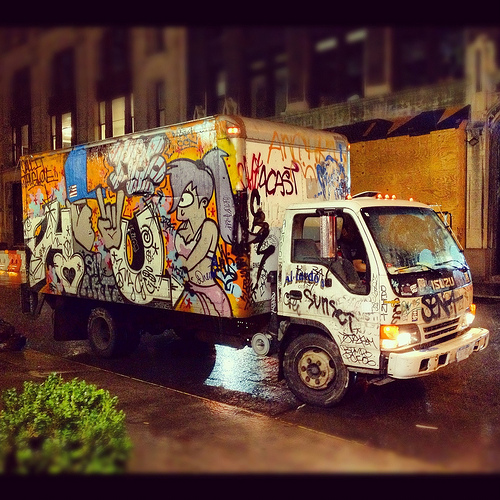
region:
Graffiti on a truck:
[191, 277, 256, 335]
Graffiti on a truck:
[298, 276, 338, 321]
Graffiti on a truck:
[332, 326, 382, 397]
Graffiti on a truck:
[394, 291, 493, 317]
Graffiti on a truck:
[124, 274, 191, 299]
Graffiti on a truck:
[150, 160, 245, 307]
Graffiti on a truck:
[243, 143, 335, 200]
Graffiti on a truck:
[93, 149, 186, 205]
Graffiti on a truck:
[61, 166, 121, 243]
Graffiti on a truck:
[25, 238, 110, 295]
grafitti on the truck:
[12, 110, 494, 414]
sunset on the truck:
[301, 286, 358, 330]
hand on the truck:
[90, 183, 123, 255]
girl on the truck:
[161, 147, 235, 312]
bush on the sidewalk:
[15, 365, 132, 476]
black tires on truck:
[78, 302, 123, 361]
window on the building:
[37, 104, 81, 154]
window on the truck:
[288, 208, 360, 273]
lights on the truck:
[380, 322, 420, 352]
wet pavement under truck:
[195, 351, 270, 396]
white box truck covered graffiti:
[13, 117, 464, 370]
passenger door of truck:
[280, 209, 390, 365]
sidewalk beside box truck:
[13, 348, 434, 484]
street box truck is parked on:
[3, 285, 488, 447]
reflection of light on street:
[207, 342, 267, 391]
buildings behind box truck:
[13, 21, 493, 116]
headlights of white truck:
[384, 306, 476, 343]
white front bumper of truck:
[385, 325, 494, 380]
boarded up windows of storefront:
[348, 140, 461, 243]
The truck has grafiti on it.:
[6, 110, 481, 405]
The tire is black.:
[280, 324, 351, 415]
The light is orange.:
[378, 320, 399, 337]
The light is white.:
[381, 333, 413, 354]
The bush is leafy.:
[1, 377, 128, 497]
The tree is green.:
[6, 374, 134, 477]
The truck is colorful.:
[23, 117, 497, 377]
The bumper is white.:
[395, 326, 497, 376]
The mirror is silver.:
[310, 207, 337, 271]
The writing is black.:
[256, 169, 301, 195]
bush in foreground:
[0, 365, 130, 483]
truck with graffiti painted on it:
[0, 132, 492, 411]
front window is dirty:
[362, 209, 464, 274]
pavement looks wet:
[207, 343, 289, 412]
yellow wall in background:
[357, 143, 462, 188]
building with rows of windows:
[4, 97, 125, 132]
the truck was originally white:
[247, 132, 469, 374]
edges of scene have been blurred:
[5, 25, 497, 75]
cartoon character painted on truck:
[159, 147, 257, 316]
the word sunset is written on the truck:
[301, 284, 355, 331]